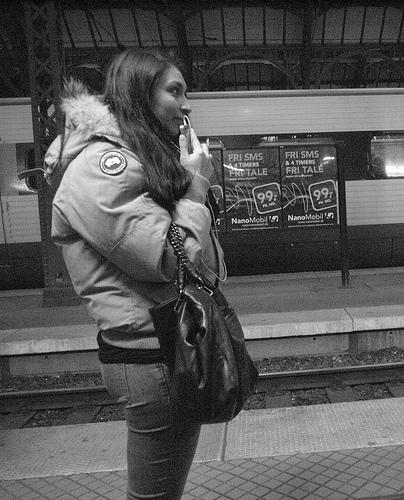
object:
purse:
[150, 230, 260, 425]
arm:
[72, 168, 227, 281]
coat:
[33, 133, 212, 352]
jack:
[197, 193, 237, 297]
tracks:
[272, 360, 402, 406]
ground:
[0, 315, 403, 497]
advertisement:
[212, 133, 346, 229]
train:
[0, 84, 403, 295]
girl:
[40, 50, 263, 498]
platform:
[0, 273, 403, 368]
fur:
[76, 88, 106, 125]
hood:
[27, 76, 126, 161]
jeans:
[95, 361, 199, 499]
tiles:
[243, 469, 361, 496]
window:
[211, 128, 402, 230]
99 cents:
[308, 177, 338, 215]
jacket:
[39, 113, 239, 354]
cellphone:
[174, 117, 200, 144]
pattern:
[272, 469, 295, 485]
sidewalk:
[0, 322, 403, 497]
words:
[284, 211, 338, 223]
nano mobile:
[282, 209, 338, 226]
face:
[152, 60, 194, 133]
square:
[107, 157, 118, 169]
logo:
[97, 148, 128, 176]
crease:
[158, 362, 179, 500]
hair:
[99, 43, 164, 200]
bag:
[148, 283, 257, 428]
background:
[200, 115, 402, 278]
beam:
[23, 0, 73, 312]